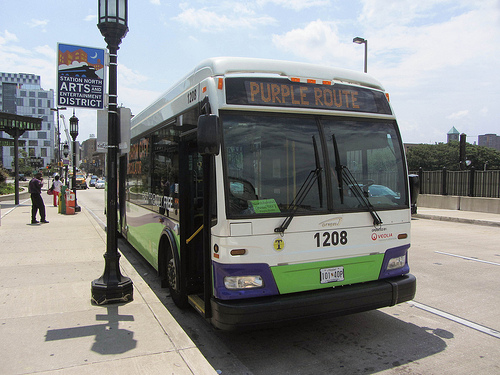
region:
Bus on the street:
[122, 68, 442, 353]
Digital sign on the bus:
[215, 66, 402, 130]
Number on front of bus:
[310, 225, 351, 249]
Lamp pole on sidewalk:
[88, 4, 158, 306]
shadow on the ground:
[42, 294, 142, 364]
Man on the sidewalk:
[22, 164, 52, 231]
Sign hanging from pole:
[31, 29, 120, 122]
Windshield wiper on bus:
[275, 143, 382, 238]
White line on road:
[405, 289, 497, 338]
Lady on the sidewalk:
[45, 171, 67, 206]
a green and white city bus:
[106, 54, 415, 333]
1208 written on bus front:
[311, 227, 348, 249]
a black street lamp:
[88, 0, 135, 308]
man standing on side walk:
[22, 170, 51, 228]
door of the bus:
[177, 123, 214, 321]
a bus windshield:
[219, 107, 412, 220]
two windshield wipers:
[270, 129, 384, 235]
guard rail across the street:
[410, 165, 499, 210]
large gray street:
[70, 164, 498, 373]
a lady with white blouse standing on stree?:
[46, 169, 69, 209]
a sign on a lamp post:
[52, 41, 109, 111]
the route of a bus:
[239, 75, 371, 112]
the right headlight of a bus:
[216, 268, 268, 296]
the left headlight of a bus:
[378, 252, 410, 275]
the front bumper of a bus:
[209, 277, 422, 315]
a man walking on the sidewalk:
[25, 171, 53, 228]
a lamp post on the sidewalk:
[89, 0, 133, 315]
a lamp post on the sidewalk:
[66, 110, 83, 215]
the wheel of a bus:
[157, 241, 194, 318]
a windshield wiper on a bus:
[327, 130, 389, 230]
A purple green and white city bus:
[116, 60, 423, 330]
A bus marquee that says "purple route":
[243, 71, 376, 121]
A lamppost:
[88, 3, 138, 308]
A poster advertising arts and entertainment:
[51, 36, 113, 115]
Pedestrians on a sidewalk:
[26, 165, 68, 230]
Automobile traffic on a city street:
[63, 163, 108, 198]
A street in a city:
[61, 163, 496, 370]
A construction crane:
[56, 110, 77, 155]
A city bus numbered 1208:
[113, 59, 420, 344]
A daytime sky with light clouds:
[3, 10, 493, 154]